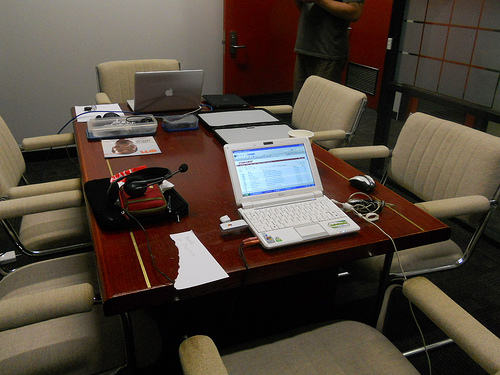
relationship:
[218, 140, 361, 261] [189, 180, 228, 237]
laptop on table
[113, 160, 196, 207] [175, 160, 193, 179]
headphone with mic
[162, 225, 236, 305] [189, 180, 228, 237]
paper on table